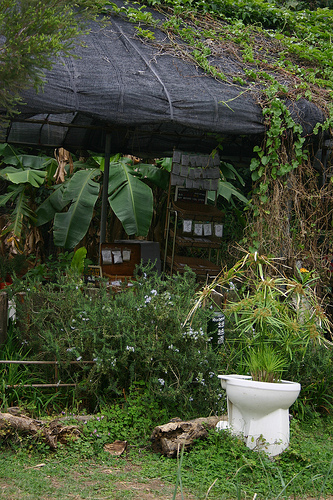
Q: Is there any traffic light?
A: No, there are no traffic lights.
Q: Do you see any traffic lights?
A: No, there are no traffic lights.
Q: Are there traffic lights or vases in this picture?
A: No, there are no traffic lights or vases.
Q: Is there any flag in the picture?
A: No, there are no flags.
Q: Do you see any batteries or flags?
A: No, there are no flags or batteries.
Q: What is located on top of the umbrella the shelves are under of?
A: The plants are on top of the umbrella.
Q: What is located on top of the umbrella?
A: The plants are on top of the umbrella.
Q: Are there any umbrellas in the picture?
A: Yes, there is an umbrella.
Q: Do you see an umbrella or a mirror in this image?
A: Yes, there is an umbrella.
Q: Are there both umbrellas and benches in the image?
A: No, there is an umbrella but no benches.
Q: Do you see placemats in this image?
A: No, there are no placemats.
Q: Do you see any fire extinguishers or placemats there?
A: No, there are no placemats or fire extinguishers.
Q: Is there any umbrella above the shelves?
A: Yes, there is an umbrella above the shelves.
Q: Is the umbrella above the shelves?
A: Yes, the umbrella is above the shelves.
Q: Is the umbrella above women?
A: No, the umbrella is above the shelves.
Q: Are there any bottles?
A: No, there are no bottles.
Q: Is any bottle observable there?
A: No, there are no bottles.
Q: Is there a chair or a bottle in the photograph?
A: No, there are no bottles or chairs.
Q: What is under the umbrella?
A: The shelves are under the umbrella.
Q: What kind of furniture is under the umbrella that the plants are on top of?
A: The pieces of furniture are shelves.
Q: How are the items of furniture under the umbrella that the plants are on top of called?
A: The pieces of furniture are shelves.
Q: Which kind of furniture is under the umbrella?
A: The pieces of furniture are shelves.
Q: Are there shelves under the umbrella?
A: Yes, there are shelves under the umbrella.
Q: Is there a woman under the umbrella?
A: No, there are shelves under the umbrella.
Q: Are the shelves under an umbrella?
A: Yes, the shelves are under an umbrella.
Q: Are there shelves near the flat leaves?
A: Yes, there are shelves near the leaves.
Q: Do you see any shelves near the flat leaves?
A: Yes, there are shelves near the leaves.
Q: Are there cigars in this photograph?
A: No, there are no cigars.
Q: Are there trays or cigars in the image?
A: No, there are no cigars or trays.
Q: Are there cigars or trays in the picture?
A: No, there are no cigars or trays.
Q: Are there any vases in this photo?
A: No, there are no vases.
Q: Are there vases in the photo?
A: No, there are no vases.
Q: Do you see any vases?
A: No, there are no vases.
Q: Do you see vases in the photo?
A: No, there are no vases.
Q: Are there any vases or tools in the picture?
A: No, there are no vases or tools.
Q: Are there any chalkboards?
A: No, there are no chalkboards.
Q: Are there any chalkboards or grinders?
A: No, there are no chalkboards or grinders.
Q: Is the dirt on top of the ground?
A: Yes, the dirt is on top of the ground.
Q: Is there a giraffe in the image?
A: No, there are no giraffes.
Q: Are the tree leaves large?
A: Yes, the tree leaves are large.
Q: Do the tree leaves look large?
A: Yes, the tree leaves are large.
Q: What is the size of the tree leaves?
A: The tree leaves are large.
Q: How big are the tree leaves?
A: The tree leaves are large.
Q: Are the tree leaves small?
A: No, the tree leaves are large.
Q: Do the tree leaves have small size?
A: No, the tree leaves are large.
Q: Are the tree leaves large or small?
A: The tree leaves are large.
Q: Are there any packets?
A: No, there are no packets.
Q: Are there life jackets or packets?
A: No, there are no packets or life jackets.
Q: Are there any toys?
A: No, there are no toys.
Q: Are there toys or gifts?
A: No, there are no toys or gifts.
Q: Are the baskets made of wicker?
A: Yes, the baskets are made of wicker.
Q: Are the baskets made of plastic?
A: No, the baskets are made of wicker.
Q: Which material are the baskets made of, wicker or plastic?
A: The baskets are made of wicker.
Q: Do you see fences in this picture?
A: Yes, there is a fence.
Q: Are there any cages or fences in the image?
A: Yes, there is a fence.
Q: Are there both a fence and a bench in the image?
A: No, there is a fence but no benches.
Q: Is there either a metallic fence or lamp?
A: Yes, there is a metal fence.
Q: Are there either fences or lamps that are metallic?
A: Yes, the fence is metallic.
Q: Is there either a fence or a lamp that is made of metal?
A: Yes, the fence is made of metal.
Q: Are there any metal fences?
A: Yes, there is a metal fence.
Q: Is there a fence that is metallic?
A: Yes, there is a fence that is metallic.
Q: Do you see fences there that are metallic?
A: Yes, there is a fence that is metallic.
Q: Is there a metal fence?
A: Yes, there is a fence that is made of metal.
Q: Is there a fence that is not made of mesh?
A: Yes, there is a fence that is made of metal.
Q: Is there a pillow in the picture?
A: No, there are no pillows.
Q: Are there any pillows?
A: No, there are no pillows.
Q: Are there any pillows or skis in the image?
A: No, there are no pillows or skis.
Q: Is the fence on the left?
A: Yes, the fence is on the left of the image.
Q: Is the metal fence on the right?
A: No, the fence is on the left of the image.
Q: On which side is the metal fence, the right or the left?
A: The fence is on the left of the image.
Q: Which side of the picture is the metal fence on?
A: The fence is on the left of the image.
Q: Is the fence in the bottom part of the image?
A: Yes, the fence is in the bottom of the image.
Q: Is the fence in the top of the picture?
A: No, the fence is in the bottom of the image.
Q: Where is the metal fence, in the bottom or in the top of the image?
A: The fence is in the bottom of the image.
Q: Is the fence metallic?
A: Yes, the fence is metallic.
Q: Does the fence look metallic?
A: Yes, the fence is metallic.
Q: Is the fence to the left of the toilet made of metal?
A: Yes, the fence is made of metal.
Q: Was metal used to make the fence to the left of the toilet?
A: Yes, the fence is made of metal.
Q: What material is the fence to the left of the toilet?
A: The fence is made of metal.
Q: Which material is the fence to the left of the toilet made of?
A: The fence is made of metal.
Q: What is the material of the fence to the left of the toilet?
A: The fence is made of metal.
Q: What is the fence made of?
A: The fence is made of metal.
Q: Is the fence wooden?
A: No, the fence is metallic.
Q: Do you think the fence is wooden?
A: No, the fence is metallic.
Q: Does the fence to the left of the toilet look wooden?
A: No, the fence is metallic.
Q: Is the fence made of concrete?
A: No, the fence is made of metal.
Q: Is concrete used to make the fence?
A: No, the fence is made of metal.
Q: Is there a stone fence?
A: No, there is a fence but it is made of metal.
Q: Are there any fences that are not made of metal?
A: No, there is a fence but it is made of metal.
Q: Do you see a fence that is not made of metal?
A: No, there is a fence but it is made of metal.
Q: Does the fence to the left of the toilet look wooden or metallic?
A: The fence is metallic.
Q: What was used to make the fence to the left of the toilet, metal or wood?
A: The fence is made of metal.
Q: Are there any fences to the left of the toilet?
A: Yes, there is a fence to the left of the toilet.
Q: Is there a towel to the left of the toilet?
A: No, there is a fence to the left of the toilet.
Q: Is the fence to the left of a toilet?
A: Yes, the fence is to the left of a toilet.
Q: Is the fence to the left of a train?
A: No, the fence is to the left of a toilet.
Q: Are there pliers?
A: No, there are no pliers.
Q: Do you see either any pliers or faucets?
A: No, there are no pliers or faucets.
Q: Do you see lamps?
A: No, there are no lamps.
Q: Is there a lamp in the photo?
A: No, there are no lamps.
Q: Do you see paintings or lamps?
A: No, there are no lamps or paintings.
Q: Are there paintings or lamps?
A: No, there are no lamps or paintings.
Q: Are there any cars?
A: No, there are no cars.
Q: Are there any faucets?
A: No, there are no faucets.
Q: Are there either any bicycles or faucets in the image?
A: No, there are no faucets or bicycles.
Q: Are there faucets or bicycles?
A: No, there are no faucets or bicycles.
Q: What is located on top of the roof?
A: The leaves are on top of the roof.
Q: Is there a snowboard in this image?
A: No, there are no snowboards.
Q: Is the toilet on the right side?
A: Yes, the toilet is on the right of the image.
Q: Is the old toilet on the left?
A: No, the toilet is on the right of the image.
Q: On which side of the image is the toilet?
A: The toilet is on the right of the image.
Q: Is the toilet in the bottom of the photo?
A: Yes, the toilet is in the bottom of the image.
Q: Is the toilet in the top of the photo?
A: No, the toilet is in the bottom of the image.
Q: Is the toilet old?
A: Yes, the toilet is old.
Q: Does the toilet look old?
A: Yes, the toilet is old.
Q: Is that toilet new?
A: No, the toilet is old.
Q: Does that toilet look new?
A: No, the toilet is old.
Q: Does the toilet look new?
A: No, the toilet is old.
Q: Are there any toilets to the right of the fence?
A: Yes, there is a toilet to the right of the fence.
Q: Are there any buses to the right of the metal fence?
A: No, there is a toilet to the right of the fence.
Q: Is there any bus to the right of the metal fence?
A: No, there is a toilet to the right of the fence.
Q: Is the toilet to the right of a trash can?
A: No, the toilet is to the right of the fence.